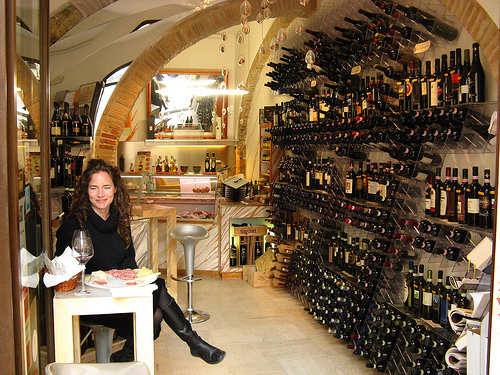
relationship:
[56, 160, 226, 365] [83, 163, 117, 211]
woman has head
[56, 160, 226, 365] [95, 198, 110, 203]
woman has mouth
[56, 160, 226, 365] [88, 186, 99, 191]
woman has eye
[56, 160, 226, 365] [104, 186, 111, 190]
woman has eye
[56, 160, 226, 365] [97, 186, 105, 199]
woman has nose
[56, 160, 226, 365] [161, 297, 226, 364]
woman has boot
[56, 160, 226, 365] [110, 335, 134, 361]
woman has boot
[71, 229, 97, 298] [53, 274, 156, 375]
wine glass on table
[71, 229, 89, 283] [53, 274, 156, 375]
wine glass on table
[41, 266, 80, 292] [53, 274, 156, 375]
basket on table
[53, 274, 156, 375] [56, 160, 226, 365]
table in front of woman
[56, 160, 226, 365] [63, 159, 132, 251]
woman has hair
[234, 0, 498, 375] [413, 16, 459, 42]
wall has wine bottle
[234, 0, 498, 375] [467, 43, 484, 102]
wall has wine bottle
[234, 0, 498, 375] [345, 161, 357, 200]
wall has wine bottle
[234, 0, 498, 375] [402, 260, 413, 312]
wall has wine bottle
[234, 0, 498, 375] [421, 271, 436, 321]
wall has wine bottle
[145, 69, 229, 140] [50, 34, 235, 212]
mirror on wall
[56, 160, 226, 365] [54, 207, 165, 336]
woman wearing dress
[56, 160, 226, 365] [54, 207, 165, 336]
woman in dress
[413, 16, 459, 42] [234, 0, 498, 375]
wine bottle on wall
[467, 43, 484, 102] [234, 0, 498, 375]
wine bottle on wall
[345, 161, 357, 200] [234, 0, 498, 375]
wine bottle on wall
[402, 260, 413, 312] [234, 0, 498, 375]
wine bottle on wall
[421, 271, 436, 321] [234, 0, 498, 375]
wine bottle on wall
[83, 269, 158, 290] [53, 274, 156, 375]
plate on table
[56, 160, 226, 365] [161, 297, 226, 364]
woman wearing boot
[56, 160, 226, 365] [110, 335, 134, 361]
woman wearing boot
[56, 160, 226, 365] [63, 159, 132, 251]
woman with hair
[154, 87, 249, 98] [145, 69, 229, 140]
light in mirror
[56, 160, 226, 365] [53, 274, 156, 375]
woman at table